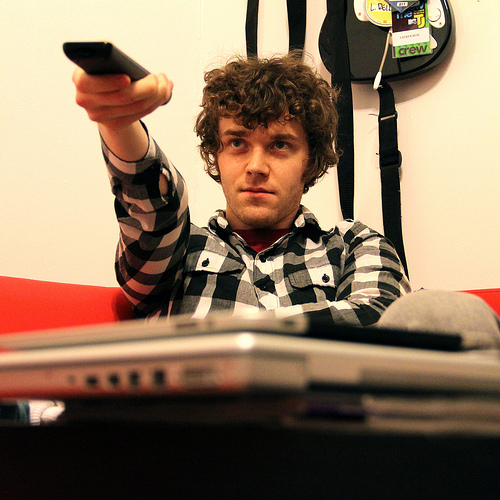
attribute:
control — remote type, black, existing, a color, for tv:
[63, 43, 174, 107]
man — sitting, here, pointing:
[101, 49, 413, 327]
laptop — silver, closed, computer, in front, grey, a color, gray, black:
[3, 309, 495, 401]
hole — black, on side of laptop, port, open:
[87, 374, 101, 388]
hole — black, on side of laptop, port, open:
[109, 374, 120, 389]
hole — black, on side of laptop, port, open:
[130, 372, 140, 388]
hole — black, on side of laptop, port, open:
[154, 371, 166, 385]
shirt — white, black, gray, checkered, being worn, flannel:
[100, 125, 413, 332]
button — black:
[203, 259, 210, 267]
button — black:
[323, 272, 331, 284]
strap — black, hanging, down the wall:
[245, 3, 259, 61]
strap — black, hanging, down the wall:
[288, 3, 308, 59]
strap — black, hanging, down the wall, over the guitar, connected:
[318, 4, 356, 220]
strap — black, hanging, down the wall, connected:
[377, 80, 410, 285]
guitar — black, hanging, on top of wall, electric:
[318, 3, 453, 83]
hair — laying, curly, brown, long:
[195, 48, 343, 195]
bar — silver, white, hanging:
[372, 26, 393, 91]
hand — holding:
[74, 67, 174, 120]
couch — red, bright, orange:
[2, 276, 497, 333]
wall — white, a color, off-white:
[5, 3, 495, 290]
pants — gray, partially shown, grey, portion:
[374, 290, 497, 351]